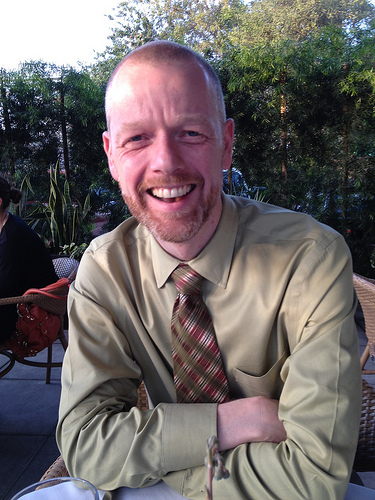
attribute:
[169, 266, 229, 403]
tie — plaid, burgandy, red, grey, striped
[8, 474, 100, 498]
glass — clear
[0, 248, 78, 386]
chair — red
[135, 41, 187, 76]
hair — brown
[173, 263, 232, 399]
tie — red and green, plaid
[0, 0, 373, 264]
greenery — lush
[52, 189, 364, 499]
dress shirt — olive green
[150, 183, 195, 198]
teeth — white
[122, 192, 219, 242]
beard — brown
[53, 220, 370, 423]
shirt — green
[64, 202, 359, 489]
shirt — green, long-sleeved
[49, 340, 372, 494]
arms — folded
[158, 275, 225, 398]
tie — green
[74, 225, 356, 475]
shirt — green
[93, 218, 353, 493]
shirt — green